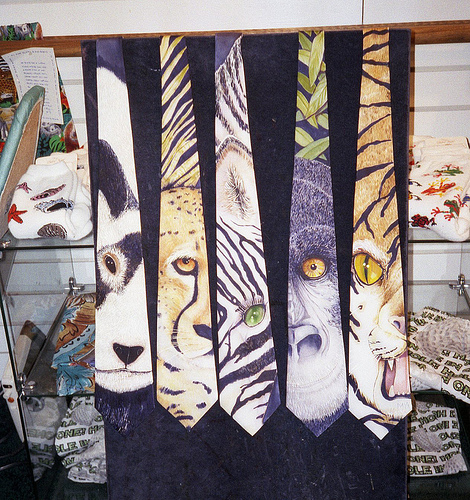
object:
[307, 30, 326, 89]
leaves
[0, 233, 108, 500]
shelving unit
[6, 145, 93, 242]
blanket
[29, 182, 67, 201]
sea shells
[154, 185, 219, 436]
cheetah face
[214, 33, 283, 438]
tie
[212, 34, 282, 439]
zebra image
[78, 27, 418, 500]
board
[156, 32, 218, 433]
cheetah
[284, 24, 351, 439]
gorilla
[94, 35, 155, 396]
panda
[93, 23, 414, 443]
five ties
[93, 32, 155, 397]
tie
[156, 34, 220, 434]
tie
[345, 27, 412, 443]
tie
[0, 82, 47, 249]
ironing board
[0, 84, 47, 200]
cover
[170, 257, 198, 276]
eye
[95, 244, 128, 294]
eye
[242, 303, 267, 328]
eye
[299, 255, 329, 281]
eye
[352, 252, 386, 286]
eye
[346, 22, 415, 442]
image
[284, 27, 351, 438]
tie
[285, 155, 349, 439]
face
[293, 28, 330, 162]
leaf pattern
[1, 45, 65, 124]
paper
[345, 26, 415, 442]
tiger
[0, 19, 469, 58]
bar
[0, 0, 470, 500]
wall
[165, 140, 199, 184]
stripe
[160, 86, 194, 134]
stripe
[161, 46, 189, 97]
stripe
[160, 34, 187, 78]
stripe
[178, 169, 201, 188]
stripe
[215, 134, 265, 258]
ear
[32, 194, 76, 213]
shells print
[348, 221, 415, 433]
tiger face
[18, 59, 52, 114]
writing